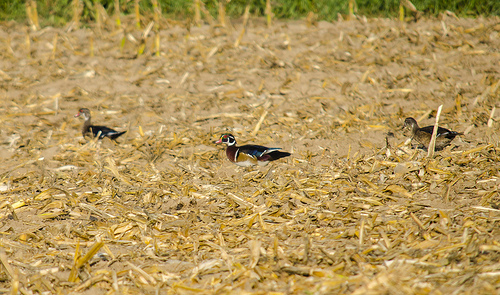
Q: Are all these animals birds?
A: Yes, all the animals are birds.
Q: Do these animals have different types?
A: No, all the animals are birds.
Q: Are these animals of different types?
A: No, all the animals are birds.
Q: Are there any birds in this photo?
A: Yes, there is a bird.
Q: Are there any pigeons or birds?
A: Yes, there is a bird.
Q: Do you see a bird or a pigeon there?
A: Yes, there is a bird.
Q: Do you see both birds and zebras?
A: No, there is a bird but no zebras.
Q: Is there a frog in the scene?
A: No, there are no frogs.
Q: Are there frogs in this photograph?
A: No, there are no frogs.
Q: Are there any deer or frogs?
A: No, there are no frogs or deer.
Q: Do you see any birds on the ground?
A: Yes, there is a bird on the ground.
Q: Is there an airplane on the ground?
A: No, there is a bird on the ground.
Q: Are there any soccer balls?
A: No, there are no soccer balls.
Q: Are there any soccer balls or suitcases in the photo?
A: No, there are no soccer balls or suitcases.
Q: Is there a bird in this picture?
A: Yes, there is a bird.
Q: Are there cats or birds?
A: Yes, there is a bird.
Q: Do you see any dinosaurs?
A: No, there are no dinosaurs.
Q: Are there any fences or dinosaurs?
A: No, there are no dinosaurs or fences.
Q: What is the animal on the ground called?
A: The animal is a bird.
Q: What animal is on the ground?
A: The animal is a bird.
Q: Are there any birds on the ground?
A: Yes, there is a bird on the ground.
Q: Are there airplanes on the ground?
A: No, there is a bird on the ground.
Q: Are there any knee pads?
A: No, there are no knee pads.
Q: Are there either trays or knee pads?
A: No, there are no knee pads or trays.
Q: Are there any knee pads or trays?
A: No, there are no knee pads or trays.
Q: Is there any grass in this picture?
A: Yes, there is grass.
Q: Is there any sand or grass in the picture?
A: Yes, there is grass.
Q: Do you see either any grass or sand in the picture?
A: Yes, there is grass.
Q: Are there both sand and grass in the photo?
A: No, there is grass but no sand.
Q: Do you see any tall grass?
A: Yes, there is tall grass.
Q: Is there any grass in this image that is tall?
A: Yes, there is grass that is tall.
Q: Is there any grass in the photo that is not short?
A: Yes, there is tall grass.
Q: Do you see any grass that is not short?
A: Yes, there is tall grass.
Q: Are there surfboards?
A: No, there are no surfboards.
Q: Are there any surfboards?
A: No, there are no surfboards.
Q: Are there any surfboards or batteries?
A: No, there are no surfboards or batteries.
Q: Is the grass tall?
A: Yes, the grass is tall.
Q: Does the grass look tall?
A: Yes, the grass is tall.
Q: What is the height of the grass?
A: The grass is tall.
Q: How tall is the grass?
A: The grass is tall.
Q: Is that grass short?
A: No, the grass is tall.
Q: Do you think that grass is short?
A: No, the grass is tall.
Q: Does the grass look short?
A: No, the grass is tall.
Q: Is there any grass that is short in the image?
A: No, there is grass but it is tall.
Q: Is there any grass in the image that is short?
A: No, there is grass but it is tall.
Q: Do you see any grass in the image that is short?
A: No, there is grass but it is tall.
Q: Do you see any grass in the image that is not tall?
A: No, there is grass but it is tall.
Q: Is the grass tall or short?
A: The grass is tall.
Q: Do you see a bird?
A: Yes, there is a bird.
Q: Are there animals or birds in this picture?
A: Yes, there is a bird.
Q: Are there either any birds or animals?
A: Yes, there is a bird.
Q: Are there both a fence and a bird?
A: No, there is a bird but no fences.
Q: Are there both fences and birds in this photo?
A: No, there is a bird but no fences.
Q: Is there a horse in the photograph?
A: No, there are no horses.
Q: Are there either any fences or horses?
A: No, there are no horses or fences.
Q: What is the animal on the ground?
A: The animal is a bird.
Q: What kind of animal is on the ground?
A: The animal is a bird.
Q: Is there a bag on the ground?
A: No, there is a bird on the ground.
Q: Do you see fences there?
A: No, there are no fences.